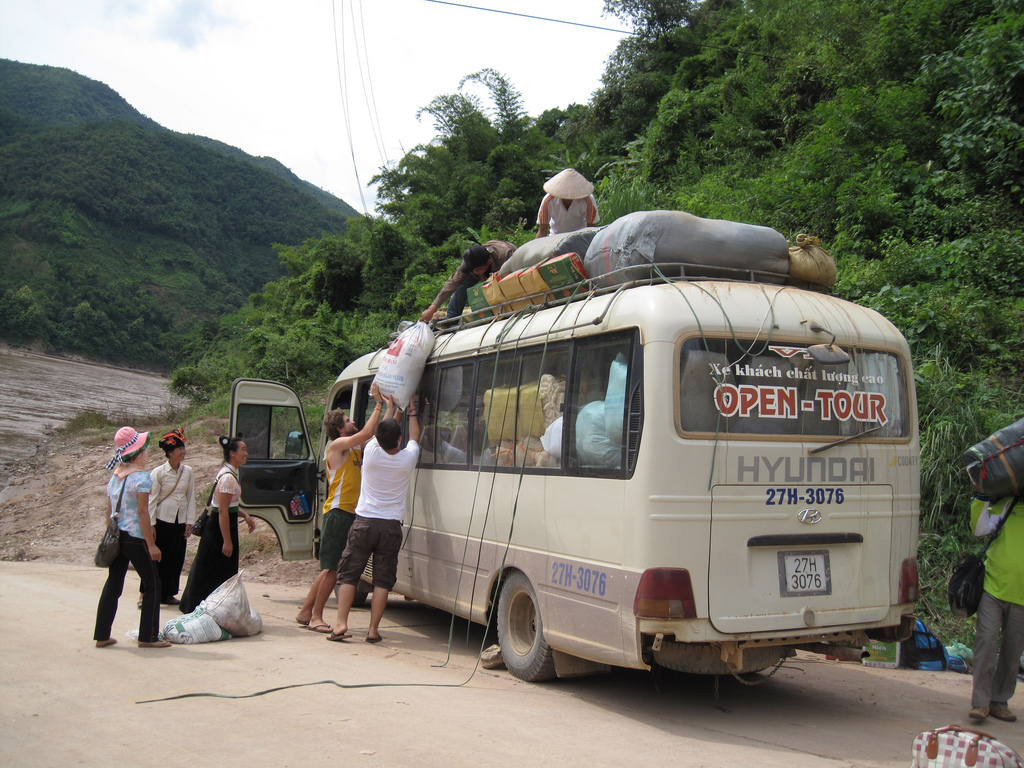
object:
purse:
[91, 468, 138, 575]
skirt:
[177, 501, 246, 626]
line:
[336, 110, 359, 168]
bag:
[892, 708, 1020, 768]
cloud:
[244, 32, 319, 112]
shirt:
[352, 448, 424, 523]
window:
[666, 327, 926, 452]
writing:
[710, 379, 893, 429]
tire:
[482, 561, 563, 689]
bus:
[212, 258, 937, 690]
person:
[944, 411, 1024, 734]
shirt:
[963, 492, 1024, 612]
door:
[217, 372, 333, 565]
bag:
[154, 605, 233, 646]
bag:
[196, 567, 264, 642]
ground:
[0, 542, 1024, 768]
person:
[87, 417, 170, 656]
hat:
[110, 422, 153, 463]